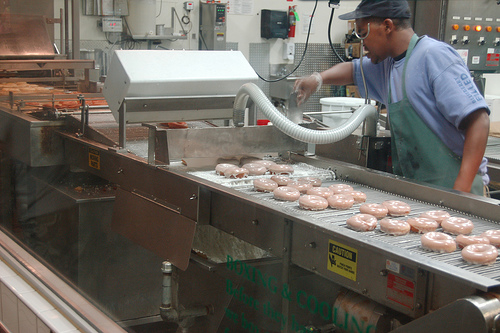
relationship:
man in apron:
[354, 0, 488, 192] [386, 101, 453, 183]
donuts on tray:
[216, 160, 500, 264] [187, 157, 500, 283]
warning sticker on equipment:
[325, 238, 359, 283] [1, 1, 500, 332]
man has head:
[354, 0, 488, 192] [354, 3, 412, 63]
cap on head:
[339, 1, 412, 20] [354, 3, 412, 63]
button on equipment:
[451, 23, 461, 31] [1, 1, 500, 332]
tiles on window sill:
[1, 260, 82, 332] [1, 227, 129, 333]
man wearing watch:
[354, 0, 488, 192] [311, 73, 321, 88]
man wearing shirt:
[354, 0, 488, 192] [352, 33, 491, 184]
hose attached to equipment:
[233, 82, 378, 145] [1, 1, 500, 332]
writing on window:
[224, 254, 382, 332] [2, 1, 500, 331]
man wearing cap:
[354, 0, 488, 192] [339, 1, 412, 20]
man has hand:
[354, 0, 488, 192] [292, 71, 317, 107]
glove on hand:
[289, 69, 322, 104] [292, 71, 317, 107]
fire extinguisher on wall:
[289, 3, 297, 38] [55, 1, 358, 124]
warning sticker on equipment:
[87, 147, 102, 172] [1, 1, 500, 332]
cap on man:
[339, 1, 412, 20] [354, 0, 488, 192]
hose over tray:
[233, 82, 378, 145] [187, 157, 500, 283]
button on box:
[464, 23, 471, 31] [413, 3, 499, 75]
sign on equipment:
[387, 276, 416, 309] [1, 1, 500, 332]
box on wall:
[260, 8, 289, 38] [55, 1, 358, 124]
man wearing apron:
[354, 0, 488, 192] [386, 101, 453, 183]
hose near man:
[233, 82, 378, 145] [354, 0, 488, 192]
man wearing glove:
[354, 0, 488, 192] [289, 69, 322, 104]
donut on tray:
[298, 192, 328, 212] [187, 157, 500, 283]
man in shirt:
[354, 0, 488, 192] [352, 33, 491, 184]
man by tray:
[354, 0, 488, 192] [187, 157, 500, 283]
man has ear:
[354, 0, 488, 192] [381, 19, 395, 36]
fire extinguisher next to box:
[289, 3, 297, 38] [260, 8, 289, 38]